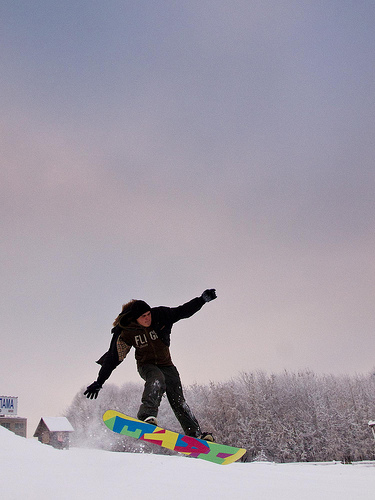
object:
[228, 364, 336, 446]
trees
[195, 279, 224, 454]
snow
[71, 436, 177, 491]
snow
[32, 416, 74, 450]
building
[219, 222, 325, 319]
sky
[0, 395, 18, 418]
letters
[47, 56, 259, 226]
sky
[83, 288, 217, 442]
boarder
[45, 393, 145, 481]
snow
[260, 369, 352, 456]
trees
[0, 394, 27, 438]
building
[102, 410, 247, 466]
design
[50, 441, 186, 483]
snow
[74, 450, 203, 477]
snow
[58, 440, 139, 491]
snow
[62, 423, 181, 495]
snow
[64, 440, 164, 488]
snow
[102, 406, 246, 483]
snow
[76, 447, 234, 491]
snow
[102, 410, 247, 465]
snowboard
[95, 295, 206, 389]
clothes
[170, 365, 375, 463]
trees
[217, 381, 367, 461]
snow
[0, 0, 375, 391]
sky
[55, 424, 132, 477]
snow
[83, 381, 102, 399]
glove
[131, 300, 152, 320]
hat